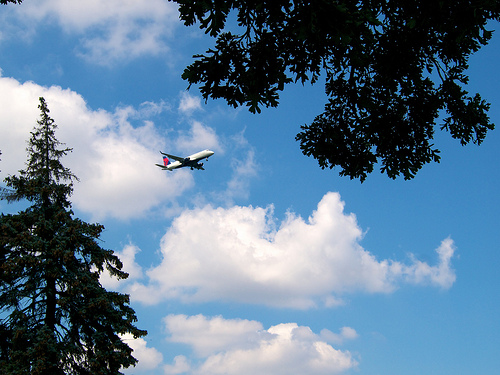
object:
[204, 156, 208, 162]
front wheel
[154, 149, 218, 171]
airplane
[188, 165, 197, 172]
wheels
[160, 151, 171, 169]
tail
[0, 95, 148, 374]
pine tree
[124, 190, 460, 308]
cloud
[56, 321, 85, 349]
branches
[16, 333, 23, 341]
leaves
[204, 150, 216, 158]
rounded nose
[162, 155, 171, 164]
paint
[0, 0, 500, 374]
sky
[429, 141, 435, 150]
leaves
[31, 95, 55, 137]
top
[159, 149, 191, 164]
wings